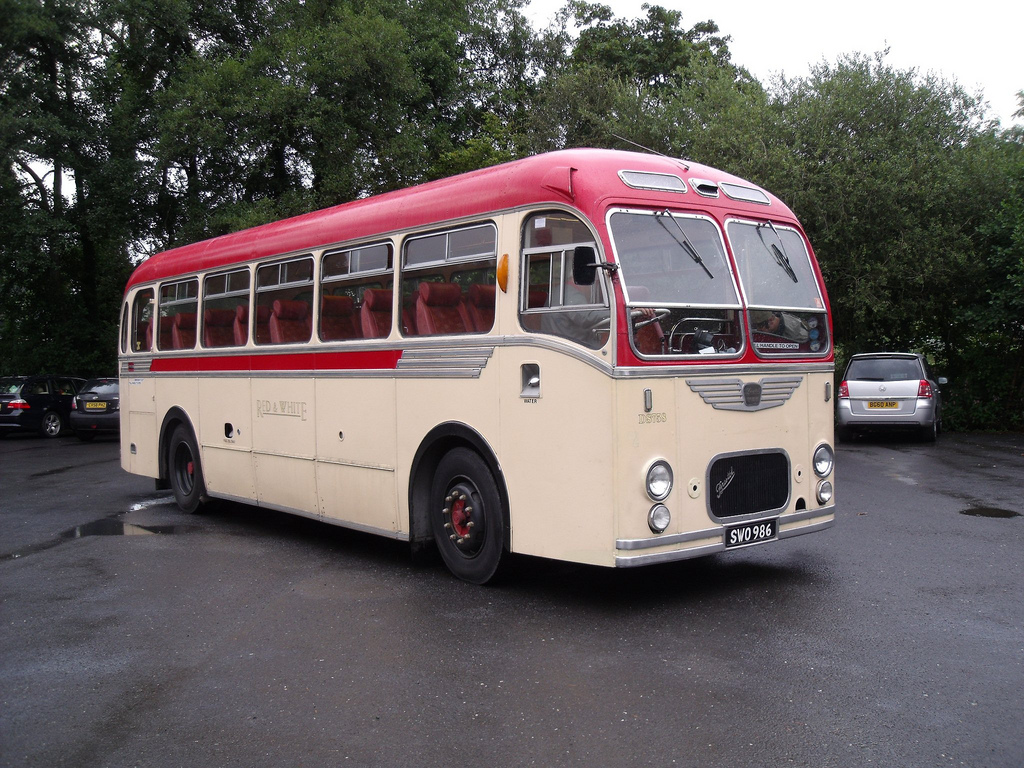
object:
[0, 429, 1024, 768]
road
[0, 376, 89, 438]
van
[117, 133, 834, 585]
bus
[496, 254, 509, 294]
light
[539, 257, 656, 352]
man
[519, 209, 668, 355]
driver's seat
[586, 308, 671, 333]
steering wheel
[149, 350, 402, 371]
stripe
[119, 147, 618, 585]
side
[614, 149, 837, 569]
front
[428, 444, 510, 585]
tire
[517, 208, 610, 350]
window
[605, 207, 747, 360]
window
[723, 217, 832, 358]
window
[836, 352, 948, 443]
back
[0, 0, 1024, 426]
leaves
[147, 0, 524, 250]
tree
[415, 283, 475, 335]
seat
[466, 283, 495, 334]
seat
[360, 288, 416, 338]
seat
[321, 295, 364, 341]
seat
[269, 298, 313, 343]
seat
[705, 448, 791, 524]
grill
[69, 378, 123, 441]
car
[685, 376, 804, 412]
wings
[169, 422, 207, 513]
tire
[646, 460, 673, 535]
light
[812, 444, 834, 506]
light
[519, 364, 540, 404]
wings